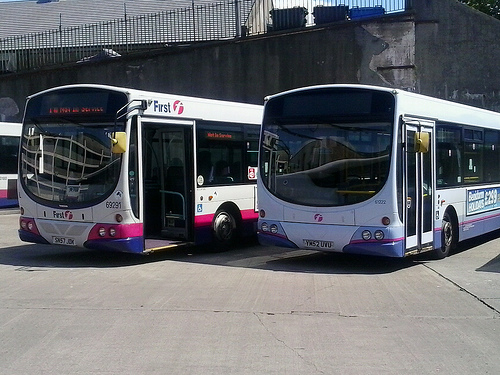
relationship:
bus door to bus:
[143, 122, 197, 251] [17, 82, 266, 261]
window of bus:
[262, 123, 391, 206] [250, 68, 492, 288]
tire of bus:
[439, 214, 466, 253] [250, 55, 499, 282]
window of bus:
[265, 120, 377, 210] [253, 79, 499, 263]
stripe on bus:
[121, 206, 262, 242] [17, 82, 266, 261]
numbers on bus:
[102, 198, 125, 215] [8, 60, 214, 289]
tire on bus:
[209, 209, 242, 249] [17, 82, 266, 261]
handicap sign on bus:
[192, 205, 205, 212] [25, 80, 260, 252]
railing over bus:
[6, 15, 398, 60] [17, 82, 266, 261]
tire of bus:
[209, 209, 242, 249] [17, 82, 266, 261]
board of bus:
[26, 82, 131, 117] [17, 82, 266, 261]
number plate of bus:
[57, 232, 77, 250] [17, 82, 266, 261]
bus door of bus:
[143, 122, 197, 251] [17, 82, 266, 261]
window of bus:
[194, 124, 247, 183] [6, 77, 264, 267]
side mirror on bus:
[410, 127, 440, 157] [253, 79, 499, 263]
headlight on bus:
[20, 220, 26, 228] [6, 77, 264, 267]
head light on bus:
[23, 213, 36, 230] [6, 77, 264, 267]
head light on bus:
[95, 222, 107, 238] [6, 77, 264, 267]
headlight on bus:
[109, 229, 116, 237] [6, 77, 264, 267]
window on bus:
[262, 123, 391, 206] [235, 87, 495, 282]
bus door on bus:
[143, 122, 197, 251] [253, 79, 499, 263]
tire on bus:
[208, 198, 245, 256] [6, 77, 264, 267]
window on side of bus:
[433, 117, 498, 188] [253, 79, 499, 263]